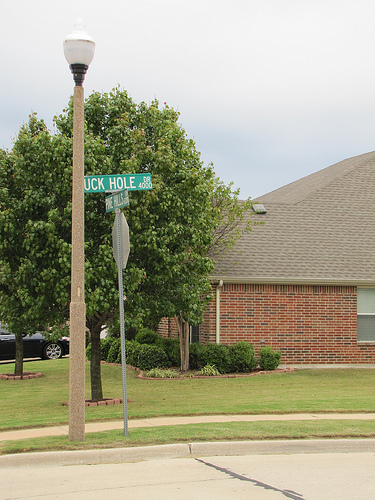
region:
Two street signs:
[82, 173, 157, 214]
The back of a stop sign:
[111, 212, 137, 435]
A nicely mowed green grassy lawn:
[156, 367, 374, 411]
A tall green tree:
[0, 85, 241, 410]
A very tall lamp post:
[57, 41, 108, 443]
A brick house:
[160, 147, 374, 368]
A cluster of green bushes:
[101, 330, 281, 371]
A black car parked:
[0, 322, 75, 362]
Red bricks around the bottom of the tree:
[0, 366, 44, 385]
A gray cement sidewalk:
[127, 407, 374, 420]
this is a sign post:
[106, 196, 136, 439]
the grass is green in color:
[173, 384, 252, 402]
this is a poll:
[61, 61, 91, 446]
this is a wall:
[284, 290, 350, 354]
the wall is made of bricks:
[295, 312, 342, 333]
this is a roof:
[287, 217, 359, 268]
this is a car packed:
[30, 342, 61, 356]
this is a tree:
[18, 162, 62, 325]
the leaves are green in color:
[12, 169, 58, 300]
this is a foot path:
[141, 417, 189, 421]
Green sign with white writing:
[69, 166, 162, 195]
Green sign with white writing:
[97, 189, 133, 214]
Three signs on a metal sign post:
[75, 155, 167, 459]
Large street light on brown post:
[45, 16, 111, 442]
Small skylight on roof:
[248, 199, 273, 217]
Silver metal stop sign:
[102, 208, 141, 274]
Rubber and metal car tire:
[38, 337, 66, 364]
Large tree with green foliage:
[0, 82, 235, 418]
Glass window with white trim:
[345, 281, 373, 348]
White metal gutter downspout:
[210, 272, 234, 356]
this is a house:
[249, 161, 373, 334]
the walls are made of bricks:
[227, 300, 353, 332]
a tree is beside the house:
[158, 129, 203, 379]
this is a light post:
[61, 34, 103, 456]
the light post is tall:
[60, 33, 99, 444]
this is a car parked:
[27, 332, 64, 364]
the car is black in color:
[23, 330, 64, 361]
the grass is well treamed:
[159, 382, 343, 405]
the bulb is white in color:
[59, 38, 98, 66]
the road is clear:
[20, 457, 363, 488]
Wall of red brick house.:
[195, 256, 373, 390]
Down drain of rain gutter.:
[209, 275, 230, 352]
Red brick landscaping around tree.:
[0, 368, 49, 384]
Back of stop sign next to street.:
[100, 212, 154, 446]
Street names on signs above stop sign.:
[85, 170, 170, 211]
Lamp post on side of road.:
[47, 5, 103, 459]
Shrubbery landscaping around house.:
[106, 321, 290, 381]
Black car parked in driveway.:
[3, 317, 75, 364]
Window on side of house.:
[344, 282, 374, 348]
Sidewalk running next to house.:
[159, 400, 371, 439]